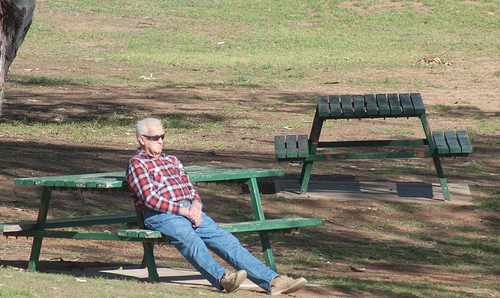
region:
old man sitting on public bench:
[130, 118, 307, 296]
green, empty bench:
[268, 92, 475, 201]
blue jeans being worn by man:
[139, 200, 279, 289]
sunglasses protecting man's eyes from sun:
[135, 131, 173, 142]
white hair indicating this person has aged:
[133, 117, 165, 133]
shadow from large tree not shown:
[14, 74, 493, 294]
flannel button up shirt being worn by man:
[128, 150, 207, 210]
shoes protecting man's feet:
[212, 271, 306, 295]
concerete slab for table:
[273, 173, 475, 207]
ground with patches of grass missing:
[276, 195, 497, 296]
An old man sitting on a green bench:
[125, 117, 302, 293]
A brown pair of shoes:
[217, 267, 304, 294]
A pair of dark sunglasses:
[141, 132, 167, 139]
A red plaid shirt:
[130, 152, 196, 214]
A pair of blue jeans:
[147, 208, 272, 289]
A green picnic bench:
[0, 165, 303, 285]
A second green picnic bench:
[272, 87, 466, 203]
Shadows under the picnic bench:
[267, 175, 437, 200]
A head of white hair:
[135, 117, 164, 134]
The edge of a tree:
[0, 0, 37, 106]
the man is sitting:
[117, 116, 306, 295]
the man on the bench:
[132, 118, 299, 297]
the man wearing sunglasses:
[117, 114, 179, 155]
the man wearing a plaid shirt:
[124, 145, 208, 208]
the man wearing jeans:
[133, 203, 286, 296]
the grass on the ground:
[85, 12, 322, 53]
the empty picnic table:
[276, 88, 468, 203]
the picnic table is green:
[250, 89, 475, 203]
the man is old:
[111, 106, 283, 273]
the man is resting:
[110, 108, 305, 296]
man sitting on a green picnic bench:
[134, 97, 310, 288]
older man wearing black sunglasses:
[135, 115, 177, 160]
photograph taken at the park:
[17, 20, 478, 274]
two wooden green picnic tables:
[21, 70, 481, 285]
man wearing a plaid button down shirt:
[120, 140, 201, 223]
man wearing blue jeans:
[133, 186, 305, 287]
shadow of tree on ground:
[25, 52, 479, 247]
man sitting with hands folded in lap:
[125, 101, 287, 282]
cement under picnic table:
[265, 160, 477, 209]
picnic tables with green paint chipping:
[22, 52, 476, 277]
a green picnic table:
[259, 88, 474, 201]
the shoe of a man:
[217, 269, 250, 290]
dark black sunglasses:
[140, 130, 169, 142]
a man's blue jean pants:
[140, 207, 280, 293]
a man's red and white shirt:
[121, 157, 201, 217]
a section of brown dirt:
[332, 255, 453, 284]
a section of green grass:
[189, 29, 384, 64]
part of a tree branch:
[2, 0, 41, 90]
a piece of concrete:
[272, 173, 467, 198]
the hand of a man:
[185, 203, 205, 225]